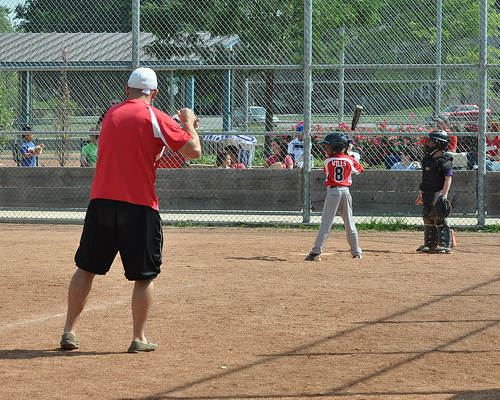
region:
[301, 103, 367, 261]
young baseball player on a field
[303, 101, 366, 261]
young baseball player at bat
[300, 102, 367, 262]
young baseball player holding a black bat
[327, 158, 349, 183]
name and number on a baseball jersey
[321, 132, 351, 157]
black helmet on a young baseball player's head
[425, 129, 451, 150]
black helmet on a baseball catcher's head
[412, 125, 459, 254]
young baseball catcher on a field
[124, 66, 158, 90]
white hat on a man's head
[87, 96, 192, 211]
red and white tshirt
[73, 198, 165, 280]
black shorts on a man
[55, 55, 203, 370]
that is a person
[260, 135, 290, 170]
that is a person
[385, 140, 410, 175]
that is a person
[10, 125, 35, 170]
that is a person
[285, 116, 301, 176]
that is a person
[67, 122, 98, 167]
that is a person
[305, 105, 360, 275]
that is a person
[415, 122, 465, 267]
that is a person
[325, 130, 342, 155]
that is a helmnet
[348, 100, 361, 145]
that is baseball bat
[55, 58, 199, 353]
man wearing red shirt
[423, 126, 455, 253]
catcher standing behind home plate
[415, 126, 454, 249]
protective gear of the catcher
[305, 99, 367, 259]
batter standing in the batter's box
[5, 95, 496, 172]
people watching the baseball game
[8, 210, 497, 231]
grass strip along the fencing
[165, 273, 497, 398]
shadows on the baseball field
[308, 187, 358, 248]
gray pants of the batter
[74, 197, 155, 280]
black shorts man is wearing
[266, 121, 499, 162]
rose bushes growing behind people watching game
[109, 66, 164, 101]
man has white cap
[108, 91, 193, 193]
red and white shirt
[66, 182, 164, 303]
coach has black shorts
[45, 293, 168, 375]
coach has grey shoes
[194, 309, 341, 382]
dirt is light brown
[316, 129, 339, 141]
batter has blue cap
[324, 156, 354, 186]
red white and black shirt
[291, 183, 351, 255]
batter has grey pants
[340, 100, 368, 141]
batter is holding bat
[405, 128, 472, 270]
catcher is standing behind home plate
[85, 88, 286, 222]
a man is wearing a red shirt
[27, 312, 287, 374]
the man is wearing slip on shoes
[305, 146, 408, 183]
the boy's jersey is #8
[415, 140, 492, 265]
the umpire is dressed in black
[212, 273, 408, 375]
the ground is made of dirt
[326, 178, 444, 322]
the boy is wearing gray pants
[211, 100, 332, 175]
the crowd is behind the fence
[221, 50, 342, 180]
the fence is made of metal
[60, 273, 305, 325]
the man has large calves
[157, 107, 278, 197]
the man is preparing to pitch